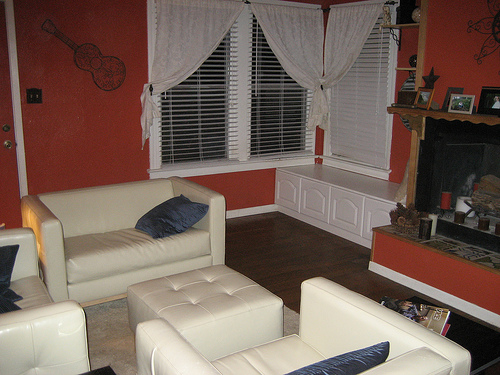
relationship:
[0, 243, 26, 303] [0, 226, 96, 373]
pillow on chair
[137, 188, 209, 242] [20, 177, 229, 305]
pillow on love seat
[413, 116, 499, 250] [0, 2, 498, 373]
fireplace in living room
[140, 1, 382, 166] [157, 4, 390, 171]
curtains on window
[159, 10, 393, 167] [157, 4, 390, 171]
blinds on windows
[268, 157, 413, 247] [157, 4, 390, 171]
window seat under window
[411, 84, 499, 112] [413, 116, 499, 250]
pictures on fireplace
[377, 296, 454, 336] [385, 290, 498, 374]
magazines on table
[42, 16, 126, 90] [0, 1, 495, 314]
decoration on walls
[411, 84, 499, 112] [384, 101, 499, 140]
pictures on shelf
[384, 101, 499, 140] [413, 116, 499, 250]
shelf above fireplace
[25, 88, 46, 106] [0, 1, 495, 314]
light switch on walls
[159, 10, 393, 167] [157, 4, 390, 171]
blinds on window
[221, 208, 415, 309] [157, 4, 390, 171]
floors near window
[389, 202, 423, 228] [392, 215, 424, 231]
pinecones in bowl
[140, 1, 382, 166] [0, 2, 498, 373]
curtains in living room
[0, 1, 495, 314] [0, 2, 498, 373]
walls of living room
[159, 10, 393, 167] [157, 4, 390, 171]
blinds over window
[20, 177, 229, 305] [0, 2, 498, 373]
love seat in living room